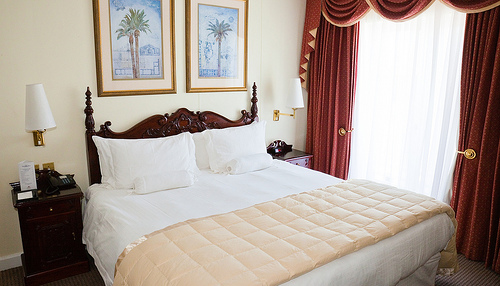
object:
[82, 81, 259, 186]
headboard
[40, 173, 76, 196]
nighstand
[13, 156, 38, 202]
telephone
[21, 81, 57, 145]
shad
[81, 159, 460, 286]
quilt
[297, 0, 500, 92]
valance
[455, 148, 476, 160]
curtain tieback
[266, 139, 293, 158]
nightstand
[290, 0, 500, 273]
curtains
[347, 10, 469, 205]
panel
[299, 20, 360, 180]
curtain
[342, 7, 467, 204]
window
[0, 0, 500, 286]
bedroom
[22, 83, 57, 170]
lamp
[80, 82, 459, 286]
bed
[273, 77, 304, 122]
light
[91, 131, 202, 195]
pillow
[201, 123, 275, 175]
pillow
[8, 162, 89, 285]
desk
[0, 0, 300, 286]
wall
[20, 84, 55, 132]
shade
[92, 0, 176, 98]
frame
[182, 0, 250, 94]
frame